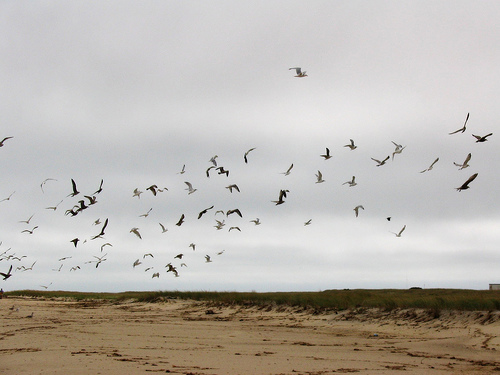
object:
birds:
[175, 214, 187, 227]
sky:
[0, 0, 500, 293]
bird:
[287, 65, 309, 79]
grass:
[0, 286, 500, 312]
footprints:
[233, 352, 243, 355]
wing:
[69, 177, 77, 192]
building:
[489, 283, 499, 295]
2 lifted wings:
[0, 264, 14, 281]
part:
[425, 341, 448, 356]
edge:
[4, 304, 12, 345]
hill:
[0, 281, 500, 330]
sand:
[0, 296, 500, 373]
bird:
[367, 153, 389, 168]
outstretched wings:
[448, 112, 471, 133]